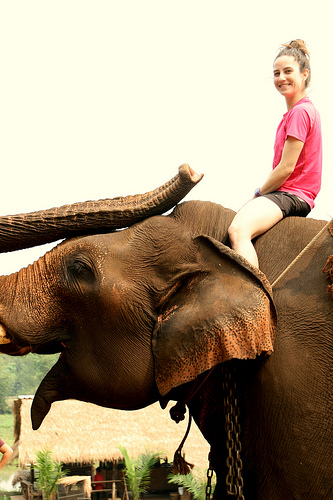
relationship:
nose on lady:
[277, 72, 286, 84] [225, 35, 322, 273]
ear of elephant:
[152, 227, 278, 398] [3, 162, 332, 495]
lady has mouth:
[225, 35, 322, 273] [276, 81, 291, 88]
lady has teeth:
[225, 35, 322, 273] [279, 83, 288, 87]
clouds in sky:
[23, 43, 220, 137] [124, 38, 192, 86]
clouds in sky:
[0, 0, 333, 271] [5, 4, 327, 274]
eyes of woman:
[268, 63, 294, 78] [204, 30, 329, 285]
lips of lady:
[278, 82, 292, 89] [225, 35, 322, 273]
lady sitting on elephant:
[225, 35, 324, 274] [3, 162, 332, 495]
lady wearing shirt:
[225, 35, 322, 273] [273, 95, 321, 209]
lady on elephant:
[225, 35, 322, 273] [3, 162, 332, 495]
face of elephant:
[3, 228, 153, 426] [3, 162, 332, 495]